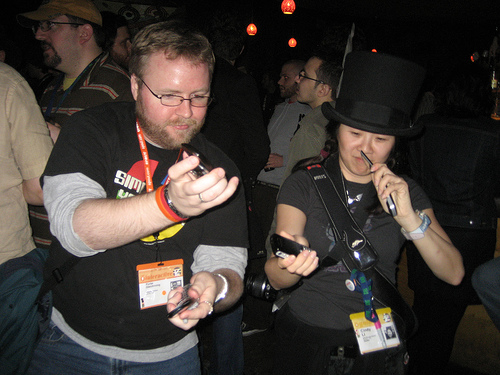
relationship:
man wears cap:
[23, 0, 137, 257] [21, 1, 108, 34]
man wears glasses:
[23, 0, 137, 257] [30, 18, 81, 35]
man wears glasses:
[279, 54, 343, 199] [295, 70, 326, 90]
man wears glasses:
[25, 18, 254, 375] [132, 70, 212, 114]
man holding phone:
[25, 18, 254, 375] [164, 279, 199, 322]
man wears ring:
[25, 18, 254, 375] [192, 191, 208, 209]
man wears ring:
[25, 18, 254, 375] [198, 299, 216, 316]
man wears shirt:
[25, 18, 254, 375] [37, 96, 250, 367]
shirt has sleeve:
[37, 96, 250, 367] [37, 111, 109, 191]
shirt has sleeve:
[37, 96, 250, 367] [198, 160, 252, 250]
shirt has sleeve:
[37, 96, 250, 367] [190, 167, 252, 294]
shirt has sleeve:
[37, 96, 250, 367] [37, 120, 114, 265]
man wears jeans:
[25, 18, 254, 375] [22, 309, 201, 374]